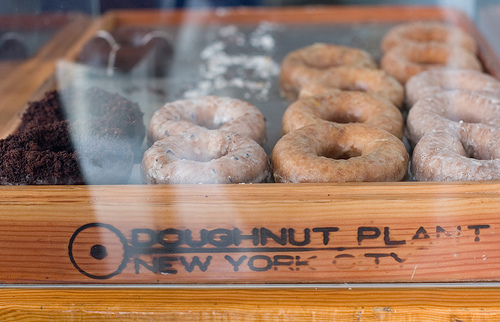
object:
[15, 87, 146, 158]
donut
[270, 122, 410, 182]
donut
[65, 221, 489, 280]
logo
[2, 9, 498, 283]
tray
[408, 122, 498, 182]
donut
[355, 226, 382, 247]
writing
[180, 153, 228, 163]
hole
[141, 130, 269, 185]
donut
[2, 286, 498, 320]
counter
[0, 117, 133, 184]
donut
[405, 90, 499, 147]
donut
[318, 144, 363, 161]
hole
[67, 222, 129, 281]
donut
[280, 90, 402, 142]
donut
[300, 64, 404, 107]
donut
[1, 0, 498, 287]
glass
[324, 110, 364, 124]
hole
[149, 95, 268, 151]
donut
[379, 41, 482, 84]
donut